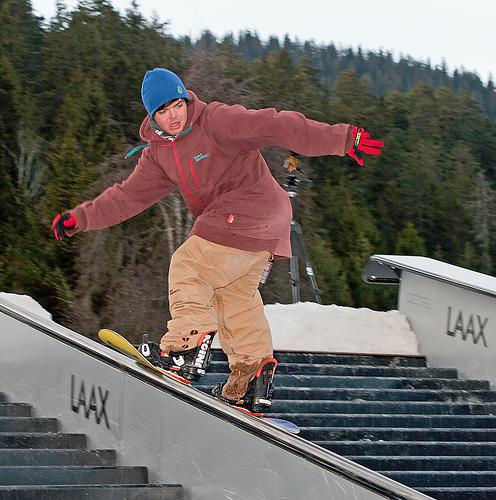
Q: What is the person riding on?
A: Snowboard.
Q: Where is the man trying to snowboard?
A: Railing of stairs.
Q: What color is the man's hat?
A: Blue.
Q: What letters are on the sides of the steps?
A: Laax.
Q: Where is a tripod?
A: Behind the man at top of stairs.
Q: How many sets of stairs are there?
A: 2.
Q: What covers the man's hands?
A: Gloves.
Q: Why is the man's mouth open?
A: Concentrating.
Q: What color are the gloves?
A: Black and red.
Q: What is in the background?
A: Forest.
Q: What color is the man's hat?
A: Blue.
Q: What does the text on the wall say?
A: LAAX.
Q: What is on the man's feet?
A: Snowboard.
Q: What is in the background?
A: Trees.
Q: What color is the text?
A: Black.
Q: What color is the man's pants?
A: Tan.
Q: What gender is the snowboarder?
A: Male.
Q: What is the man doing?
A: Snowboarding.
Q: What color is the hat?
A: Blue.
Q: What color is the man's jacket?
A: Red.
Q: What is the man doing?
A: Snowboarding.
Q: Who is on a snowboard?
A: The man.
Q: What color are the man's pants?
A: Brown.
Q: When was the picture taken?
A: Daytime.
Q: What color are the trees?
A: Green.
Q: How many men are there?
A: One.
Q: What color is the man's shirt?
A: Red.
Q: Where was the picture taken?
A: On a stairway.